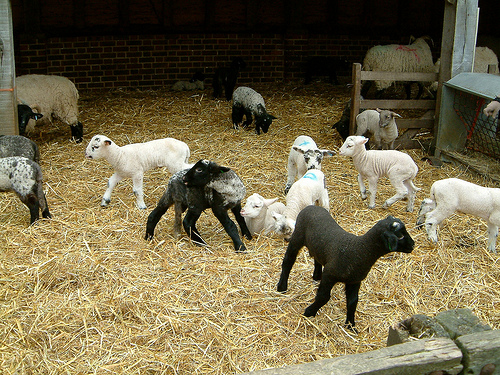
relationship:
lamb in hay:
[277, 204, 415, 329] [2, 87, 499, 373]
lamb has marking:
[285, 135, 335, 193] [298, 140, 310, 146]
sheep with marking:
[365, 33, 436, 99] [394, 42, 423, 66]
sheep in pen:
[365, 33, 436, 99] [3, 85, 499, 371]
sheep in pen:
[146, 160, 252, 251] [3, 85, 499, 371]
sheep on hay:
[365, 33, 436, 99] [2, 87, 499, 373]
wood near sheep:
[435, 1, 481, 139] [365, 33, 436, 99]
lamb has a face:
[277, 204, 415, 329] [397, 229, 415, 255]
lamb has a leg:
[277, 204, 415, 329] [303, 272, 337, 319]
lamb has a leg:
[277, 204, 415, 329] [277, 238, 304, 292]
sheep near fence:
[365, 33, 436, 99] [349, 62, 439, 151]